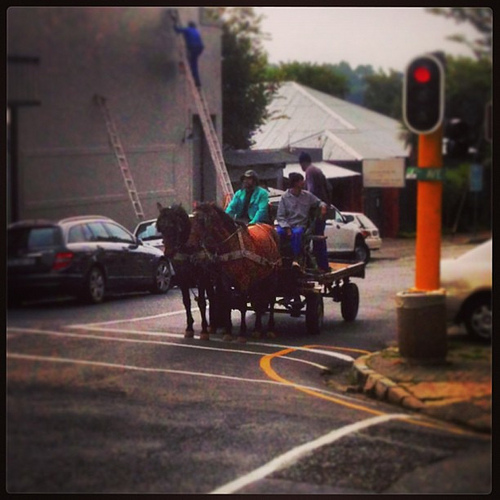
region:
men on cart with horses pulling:
[155, 166, 367, 335]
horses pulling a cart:
[151, 195, 274, 340]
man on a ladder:
[163, 9, 245, 206]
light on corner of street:
[400, 48, 454, 137]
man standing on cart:
[296, 148, 333, 273]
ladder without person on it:
[86, 95, 149, 225]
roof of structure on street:
[215, 82, 407, 159]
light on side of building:
[176, 124, 203, 149]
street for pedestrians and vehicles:
[11, 320, 365, 495]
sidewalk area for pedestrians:
[378, 243, 411, 256]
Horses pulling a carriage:
[148, 188, 288, 338]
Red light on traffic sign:
[396, 57, 446, 132]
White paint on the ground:
[111, 316, 288, 374]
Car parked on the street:
[45, 209, 169, 308]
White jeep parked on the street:
[320, 204, 372, 258]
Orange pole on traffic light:
[405, 138, 448, 282]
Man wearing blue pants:
[265, 223, 317, 263]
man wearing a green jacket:
[222, 190, 266, 215]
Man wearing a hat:
[238, 169, 257, 186]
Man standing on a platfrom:
[304, 165, 335, 272]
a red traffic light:
[385, 40, 465, 306]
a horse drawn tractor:
[122, 166, 402, 366]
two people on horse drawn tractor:
[189, 158, 325, 281]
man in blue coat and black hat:
[207, 160, 290, 232]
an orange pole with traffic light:
[395, 53, 460, 299]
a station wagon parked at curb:
[17, 200, 171, 309]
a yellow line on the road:
[241, 331, 411, 473]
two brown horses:
[129, 185, 304, 350]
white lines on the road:
[17, 302, 388, 498]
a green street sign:
[393, 159, 450, 189]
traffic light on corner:
[400, 46, 447, 143]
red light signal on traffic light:
[412, 62, 435, 87]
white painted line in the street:
[211, 413, 380, 498]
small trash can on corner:
[394, 284, 453, 369]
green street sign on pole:
[402, 161, 458, 184]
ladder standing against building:
[93, 98, 153, 218]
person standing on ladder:
[183, 33, 215, 85]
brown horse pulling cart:
[187, 200, 287, 346]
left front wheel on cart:
[300, 290, 335, 336]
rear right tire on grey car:
[79, 261, 113, 301]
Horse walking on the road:
[163, 171, 368, 346]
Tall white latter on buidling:
[86, 68, 163, 256]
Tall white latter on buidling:
[157, 8, 255, 205]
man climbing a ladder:
[163, 18, 232, 96]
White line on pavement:
[279, 405, 352, 479]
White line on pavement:
[215, 350, 258, 395]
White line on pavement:
[135, 354, 201, 389]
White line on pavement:
[42, 339, 124, 381]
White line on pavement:
[75, 318, 175, 369]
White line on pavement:
[177, 316, 303, 377]